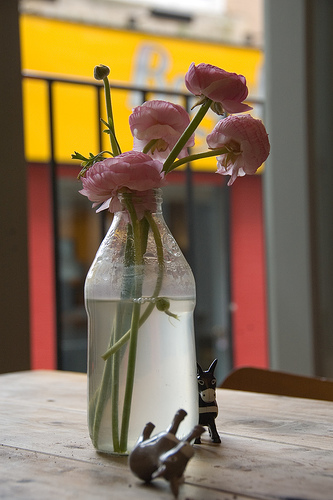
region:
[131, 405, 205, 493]
a small donkey figurine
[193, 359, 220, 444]
a small donkey figurine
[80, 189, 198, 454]
a clear glass bottle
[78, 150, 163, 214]
a small pink cut flower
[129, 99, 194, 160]
a small pink cut flower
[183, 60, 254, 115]
a small pink cut flower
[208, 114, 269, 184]
a small pink cut flower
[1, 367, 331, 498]
a brown wooden table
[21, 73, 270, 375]
a metal railing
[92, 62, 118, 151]
a green flower bud and stem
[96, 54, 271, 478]
four flowers in a vase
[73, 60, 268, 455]
four pink roses in a vase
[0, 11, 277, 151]
yellow wall in the back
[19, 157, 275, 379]
red wal in the back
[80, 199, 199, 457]
transparent vase full of water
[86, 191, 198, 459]
transparent vase with four flowers in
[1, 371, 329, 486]
brown wooden table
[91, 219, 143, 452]
green roses stems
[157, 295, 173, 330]
small green thorn in stem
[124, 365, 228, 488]
two ceramic donkeys in table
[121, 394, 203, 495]
this is a toy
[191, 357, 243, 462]
this is a toy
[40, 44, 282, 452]
this is a flower vase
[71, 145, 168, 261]
this is a flower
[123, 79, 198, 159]
this is a flower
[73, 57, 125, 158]
this is a flower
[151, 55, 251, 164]
this is a flower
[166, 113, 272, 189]
this is a flower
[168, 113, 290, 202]
the flower is pink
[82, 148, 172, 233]
the flower is pink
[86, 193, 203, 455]
transparent vase where flowers are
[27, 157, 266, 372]
red wall in the back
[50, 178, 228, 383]
gray doors in red and yellow wall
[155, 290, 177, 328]
little green thorn in stem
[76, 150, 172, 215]
pink soft flower pedals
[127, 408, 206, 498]
plastic small and brown donkey toy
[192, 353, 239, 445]
black plastic donkey sitting on the table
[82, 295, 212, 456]
clear water inside a glass vase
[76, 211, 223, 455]
green soft flower stems inside a vase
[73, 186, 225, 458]
small glass bottle turned into a vase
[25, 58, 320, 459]
flower arrangement near a large window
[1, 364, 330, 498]
brown soft wooden table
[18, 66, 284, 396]
black iron fence on a balcony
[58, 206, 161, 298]
sunlight shinning on a glass bottle